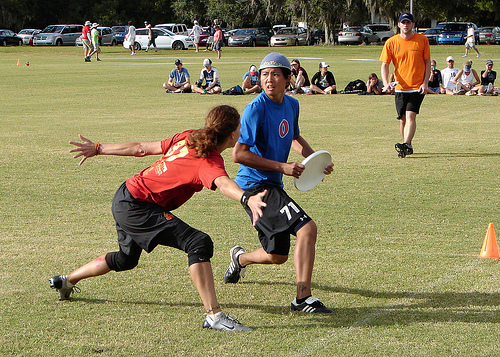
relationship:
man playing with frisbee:
[223, 52, 333, 313] [295, 151, 333, 192]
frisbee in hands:
[295, 151, 333, 192] [281, 161, 333, 183]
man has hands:
[223, 52, 333, 313] [281, 161, 333, 183]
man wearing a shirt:
[223, 52, 333, 313] [235, 89, 299, 191]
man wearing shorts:
[223, 52, 333, 313] [242, 184, 311, 255]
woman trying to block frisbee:
[48, 104, 267, 332] [295, 151, 333, 192]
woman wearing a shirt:
[48, 104, 267, 332] [125, 130, 228, 211]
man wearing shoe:
[223, 52, 333, 313] [291, 297, 334, 314]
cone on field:
[479, 223, 499, 259] [0, 43, 499, 355]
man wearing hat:
[223, 52, 333, 313] [260, 53, 293, 70]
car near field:
[123, 27, 194, 50] [0, 43, 499, 355]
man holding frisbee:
[223, 52, 333, 313] [295, 151, 333, 192]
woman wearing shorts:
[48, 104, 267, 332] [111, 181, 182, 255]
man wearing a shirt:
[379, 12, 431, 156] [378, 33, 430, 91]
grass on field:
[0, 43, 499, 356] [0, 43, 499, 355]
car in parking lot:
[123, 27, 194, 50] [1, 21, 500, 49]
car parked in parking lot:
[228, 27, 269, 45] [1, 21, 500, 49]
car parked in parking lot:
[270, 27, 311, 46] [1, 21, 500, 49]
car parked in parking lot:
[337, 25, 381, 46] [1, 21, 500, 49]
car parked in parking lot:
[33, 24, 83, 44] [1, 21, 500, 49]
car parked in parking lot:
[479, 27, 499, 44] [1, 21, 500, 49]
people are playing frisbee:
[48, 52, 334, 334] [295, 151, 333, 192]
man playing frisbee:
[223, 52, 333, 313] [295, 151, 333, 192]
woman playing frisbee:
[48, 104, 267, 332] [295, 151, 333, 192]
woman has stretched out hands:
[48, 104, 267, 332] [69, 134, 267, 224]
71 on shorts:
[280, 202, 300, 220] [242, 184, 311, 255]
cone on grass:
[479, 223, 499, 259] [0, 43, 499, 356]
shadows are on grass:
[59, 151, 499, 328] [0, 43, 499, 356]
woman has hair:
[48, 104, 267, 332] [186, 105, 239, 160]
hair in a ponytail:
[186, 105, 239, 160] [185, 125, 220, 161]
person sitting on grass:
[162, 59, 191, 93] [0, 43, 499, 356]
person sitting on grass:
[192, 58, 221, 96] [0, 43, 499, 356]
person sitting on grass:
[310, 62, 335, 96] [0, 43, 499, 356]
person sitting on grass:
[480, 60, 495, 95] [0, 43, 499, 356]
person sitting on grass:
[453, 60, 481, 96] [0, 43, 499, 356]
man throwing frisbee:
[223, 52, 333, 313] [295, 151, 333, 192]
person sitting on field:
[162, 59, 191, 93] [0, 43, 499, 355]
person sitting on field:
[192, 58, 221, 96] [0, 43, 499, 355]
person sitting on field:
[310, 62, 335, 96] [0, 43, 499, 355]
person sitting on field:
[453, 60, 481, 96] [0, 43, 499, 355]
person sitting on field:
[480, 60, 495, 95] [0, 43, 499, 355]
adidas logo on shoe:
[300, 304, 317, 313] [291, 297, 334, 314]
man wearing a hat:
[223, 52, 333, 313] [260, 53, 293, 70]